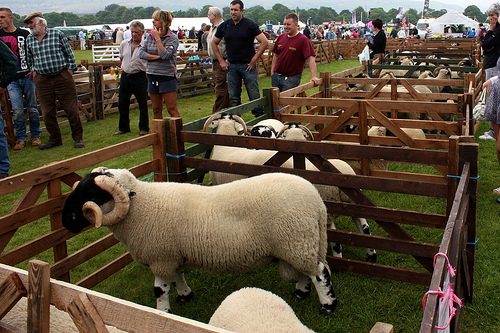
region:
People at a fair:
[34, 4, 443, 310]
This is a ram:
[57, 140, 343, 312]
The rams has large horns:
[53, 157, 139, 227]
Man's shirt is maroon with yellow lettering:
[267, 12, 307, 82]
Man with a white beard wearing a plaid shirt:
[18, 17, 77, 77]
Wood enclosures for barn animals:
[224, 67, 466, 233]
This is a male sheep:
[265, 236, 353, 318]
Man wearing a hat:
[21, 8, 55, 45]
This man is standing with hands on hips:
[208, 0, 263, 85]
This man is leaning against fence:
[268, 0, 327, 104]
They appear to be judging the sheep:
[28, 7, 470, 311]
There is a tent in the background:
[411, 5, 493, 49]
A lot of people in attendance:
[65, 4, 493, 64]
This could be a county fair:
[13, 4, 485, 331]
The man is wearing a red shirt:
[268, 28, 320, 78]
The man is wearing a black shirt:
[204, 11, 266, 81]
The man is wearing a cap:
[21, 10, 88, 31]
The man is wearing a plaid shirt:
[19, 25, 78, 80]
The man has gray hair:
[18, 9, 59, 39]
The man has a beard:
[23, 14, 79, 59]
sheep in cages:
[16, 12, 487, 304]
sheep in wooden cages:
[25, 41, 495, 330]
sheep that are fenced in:
[64, 34, 496, 307]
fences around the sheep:
[54, 38, 498, 276]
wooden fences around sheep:
[59, 4, 498, 305]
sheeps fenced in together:
[12, 51, 496, 315]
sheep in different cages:
[23, 11, 482, 331]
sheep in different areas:
[60, 12, 465, 330]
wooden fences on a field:
[47, 29, 433, 257]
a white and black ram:
[60, 163, 336, 310]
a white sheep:
[206, 283, 320, 330]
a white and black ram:
[200, 111, 377, 258]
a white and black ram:
[276, 120, 311, 142]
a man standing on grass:
[113, 19, 148, 134]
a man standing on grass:
[20, 10, 85, 150]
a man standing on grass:
[0, 6, 45, 151]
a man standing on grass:
[212, 1, 266, 103]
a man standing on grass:
[270, 11, 319, 103]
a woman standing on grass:
[140, 6, 182, 125]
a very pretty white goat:
[57, 151, 342, 313]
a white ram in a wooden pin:
[2, 115, 477, 331]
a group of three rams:
[200, 85, 382, 260]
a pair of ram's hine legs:
[277, 185, 342, 313]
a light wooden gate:
[1, 111, 173, 306]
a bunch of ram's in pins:
[1, 40, 483, 332]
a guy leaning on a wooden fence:
[263, 5, 327, 97]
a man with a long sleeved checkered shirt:
[21, 9, 88, 149]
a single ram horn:
[78, 168, 133, 235]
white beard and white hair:
[28, 15, 48, 36]